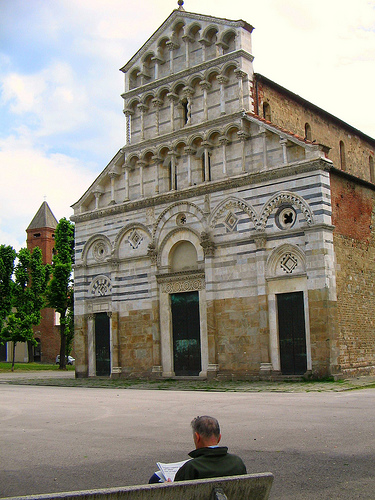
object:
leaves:
[28, 245, 45, 292]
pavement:
[0, 383, 375, 498]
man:
[148, 415, 248, 485]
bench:
[0, 470, 274, 500]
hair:
[189, 414, 221, 442]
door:
[168, 289, 203, 378]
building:
[68, 0, 375, 385]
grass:
[0, 361, 75, 375]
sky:
[21, 34, 141, 176]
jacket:
[172, 445, 248, 481]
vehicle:
[55, 354, 74, 366]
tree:
[39, 216, 75, 371]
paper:
[152, 457, 194, 484]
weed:
[129, 369, 154, 391]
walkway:
[0, 374, 375, 393]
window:
[80, 232, 116, 267]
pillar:
[204, 146, 210, 182]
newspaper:
[152, 458, 196, 485]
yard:
[0, 361, 75, 380]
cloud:
[8, 10, 113, 71]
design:
[118, 0, 257, 172]